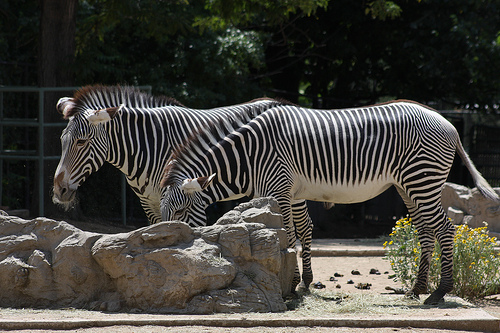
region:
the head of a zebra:
[37, 98, 129, 218]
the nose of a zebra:
[36, 163, 95, 206]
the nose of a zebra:
[46, 168, 84, 217]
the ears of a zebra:
[54, 93, 141, 153]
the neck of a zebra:
[100, 83, 190, 179]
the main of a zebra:
[72, 58, 202, 135]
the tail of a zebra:
[443, 108, 497, 233]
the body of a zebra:
[204, 75, 484, 230]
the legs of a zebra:
[382, 169, 479, 299]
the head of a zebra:
[46, 86, 143, 203]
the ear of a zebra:
[54, 95, 134, 154]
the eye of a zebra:
[57, 109, 122, 163]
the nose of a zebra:
[46, 137, 112, 219]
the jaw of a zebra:
[84, 118, 131, 181]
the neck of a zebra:
[99, 66, 181, 198]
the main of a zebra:
[73, 50, 200, 148]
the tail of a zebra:
[424, 124, 499, 212]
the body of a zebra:
[22, 54, 325, 219]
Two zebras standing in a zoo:
[49, 70, 481, 301]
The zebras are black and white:
[196, 107, 463, 206]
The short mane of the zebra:
[68, 82, 188, 117]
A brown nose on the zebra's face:
[48, 180, 78, 204]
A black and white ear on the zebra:
[178, 168, 223, 202]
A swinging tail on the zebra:
[452, 135, 497, 203]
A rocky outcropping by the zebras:
[2, 204, 309, 319]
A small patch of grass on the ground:
[298, 290, 386, 325]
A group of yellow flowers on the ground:
[387, 210, 498, 300]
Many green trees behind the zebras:
[21, 0, 477, 97]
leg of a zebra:
[423, 211, 470, 293]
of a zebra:
[400, 210, 447, 287]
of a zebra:
[293, 196, 335, 287]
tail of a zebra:
[448, 144, 496, 212]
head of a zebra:
[130, 120, 231, 241]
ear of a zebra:
[183, 162, 228, 196]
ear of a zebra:
[48, 88, 77, 110]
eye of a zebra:
[68, 127, 96, 148]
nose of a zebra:
[48, 178, 71, 195]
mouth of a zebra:
[52, 185, 88, 210]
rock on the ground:
[0, 258, 32, 308]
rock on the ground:
[23, 248, 53, 300]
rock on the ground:
[40, 219, 108, 307]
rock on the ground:
[93, 218, 230, 304]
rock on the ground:
[91, 284, 122, 312]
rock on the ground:
[193, 218, 257, 256]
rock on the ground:
[248, 227, 286, 276]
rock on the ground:
[180, 260, 288, 313]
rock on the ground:
[239, 193, 279, 231]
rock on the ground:
[86, 296, 103, 307]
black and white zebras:
[41, 37, 461, 283]